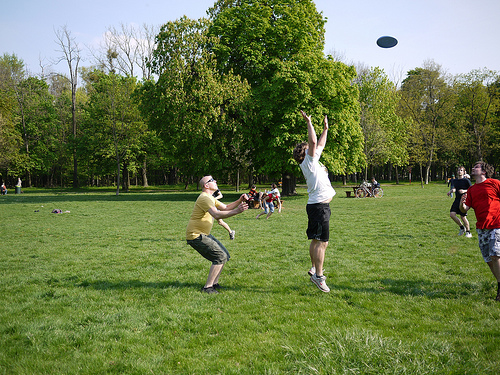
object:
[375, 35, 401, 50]
frisbee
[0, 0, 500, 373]
air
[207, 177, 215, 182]
sunglasses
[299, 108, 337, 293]
man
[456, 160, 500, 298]
man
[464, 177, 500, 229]
shirt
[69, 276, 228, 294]
shadow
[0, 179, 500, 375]
ground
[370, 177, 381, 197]
person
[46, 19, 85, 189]
tree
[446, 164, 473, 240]
person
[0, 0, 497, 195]
up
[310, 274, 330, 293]
shoe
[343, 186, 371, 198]
bench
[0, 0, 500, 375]
park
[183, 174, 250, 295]
man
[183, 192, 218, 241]
shirt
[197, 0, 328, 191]
tree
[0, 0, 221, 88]
sky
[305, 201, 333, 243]
shorts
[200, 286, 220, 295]
shoe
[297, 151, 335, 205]
shirt